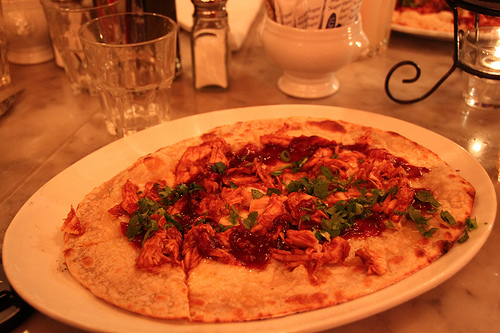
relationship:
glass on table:
[72, 15, 180, 139] [0, 42, 497, 331]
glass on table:
[39, 1, 132, 101] [0, 42, 497, 331]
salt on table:
[184, 0, 237, 93] [0, 42, 497, 331]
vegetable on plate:
[439, 206, 460, 229] [0, 104, 495, 331]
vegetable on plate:
[278, 149, 294, 163] [0, 104, 495, 331]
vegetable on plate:
[249, 185, 266, 201] [0, 104, 495, 331]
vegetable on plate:
[411, 188, 443, 212] [0, 104, 495, 331]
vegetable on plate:
[456, 230, 471, 243] [0, 104, 495, 331]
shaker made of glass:
[189, 0, 231, 95] [72, 15, 180, 139]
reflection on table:
[460, 122, 494, 157] [12, 103, 78, 160]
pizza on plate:
[67, 97, 497, 322] [0, 104, 495, 331]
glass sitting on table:
[72, 15, 181, 132] [0, 42, 497, 331]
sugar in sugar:
[267, 0, 362, 31] [267, 0, 362, 31]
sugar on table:
[267, 0, 362, 31] [0, 42, 497, 331]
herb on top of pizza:
[317, 197, 382, 244] [61, 112, 476, 330]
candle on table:
[421, 41, 498, 112] [19, 107, 76, 154]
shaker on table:
[189, 0, 231, 95] [0, 42, 497, 331]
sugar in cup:
[267, 0, 362, 24] [260, 16, 367, 100]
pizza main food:
[61, 115, 476, 323] [54, 111, 479, 323]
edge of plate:
[322, 239, 491, 331] [0, 104, 495, 331]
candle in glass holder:
[479, 36, 500, 88] [453, 14, 499, 108]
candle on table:
[479, 36, 500, 88] [0, 42, 497, 331]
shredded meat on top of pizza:
[118, 140, 413, 276] [61, 112, 476, 330]